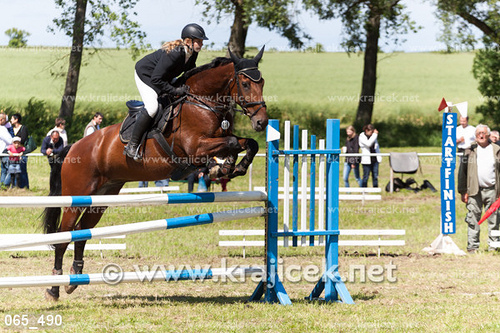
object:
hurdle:
[0, 190, 288, 304]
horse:
[33, 45, 271, 302]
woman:
[339, 126, 365, 188]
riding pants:
[132, 69, 158, 116]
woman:
[125, 23, 209, 159]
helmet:
[180, 24, 210, 39]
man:
[456, 122, 500, 253]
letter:
[446, 113, 454, 125]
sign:
[440, 112, 455, 236]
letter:
[444, 124, 455, 137]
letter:
[443, 145, 452, 158]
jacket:
[133, 42, 199, 93]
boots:
[126, 108, 154, 161]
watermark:
[104, 256, 400, 287]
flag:
[436, 97, 452, 113]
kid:
[3, 134, 27, 190]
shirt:
[6, 146, 27, 163]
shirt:
[475, 145, 496, 187]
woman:
[357, 124, 384, 187]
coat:
[357, 132, 382, 164]